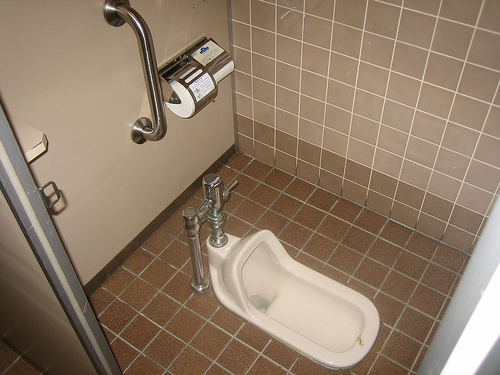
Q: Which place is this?
A: It is a restroom.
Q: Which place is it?
A: It is a restroom.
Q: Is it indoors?
A: Yes, it is indoors.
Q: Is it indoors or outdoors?
A: It is indoors.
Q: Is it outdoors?
A: No, it is indoors.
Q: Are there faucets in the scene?
A: No, there are no faucets.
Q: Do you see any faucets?
A: No, there are no faucets.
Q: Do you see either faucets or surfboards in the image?
A: No, there are no faucets or surfboards.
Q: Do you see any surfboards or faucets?
A: No, there are no faucets or surfboards.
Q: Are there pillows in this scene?
A: No, there are no pillows.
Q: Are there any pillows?
A: No, there are no pillows.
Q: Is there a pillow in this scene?
A: No, there are no pillows.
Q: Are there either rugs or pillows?
A: No, there are no pillows or rugs.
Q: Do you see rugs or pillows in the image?
A: No, there are no pillows or rugs.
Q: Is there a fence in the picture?
A: No, there are no fences.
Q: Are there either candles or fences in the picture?
A: No, there are no fences or candles.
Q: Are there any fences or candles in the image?
A: No, there are no fences or candles.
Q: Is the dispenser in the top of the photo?
A: Yes, the dispenser is in the top of the image.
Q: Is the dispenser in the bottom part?
A: No, the dispenser is in the top of the image.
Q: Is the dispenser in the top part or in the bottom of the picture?
A: The dispenser is in the top of the image.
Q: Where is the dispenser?
A: The dispenser is in the restroom.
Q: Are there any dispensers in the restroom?
A: Yes, there is a dispenser in the restroom.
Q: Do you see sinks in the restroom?
A: No, there is a dispenser in the restroom.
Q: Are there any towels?
A: No, there are no towels.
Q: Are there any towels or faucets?
A: No, there are no towels or faucets.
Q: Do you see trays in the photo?
A: No, there are no trays.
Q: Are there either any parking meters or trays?
A: No, there are no trays or parking meters.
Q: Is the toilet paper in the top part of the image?
A: Yes, the toilet paper is in the top of the image.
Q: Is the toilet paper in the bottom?
A: No, the toilet paper is in the top of the image.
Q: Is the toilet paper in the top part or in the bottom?
A: The toilet paper is in the top of the image.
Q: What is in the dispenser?
A: The toilet paper is in the dispenser.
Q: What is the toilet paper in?
A: The toilet paper is in the dispenser.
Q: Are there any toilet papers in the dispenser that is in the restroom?
A: Yes, there is a toilet paper in the dispenser.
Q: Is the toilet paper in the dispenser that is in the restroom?
A: Yes, the toilet paper is in the dispenser.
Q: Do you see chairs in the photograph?
A: No, there are no chairs.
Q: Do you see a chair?
A: No, there are no chairs.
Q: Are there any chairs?
A: No, there are no chairs.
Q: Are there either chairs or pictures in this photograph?
A: No, there are no chairs or pictures.